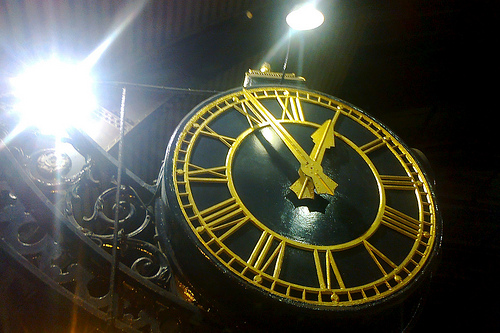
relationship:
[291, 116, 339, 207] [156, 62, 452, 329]
hand on clock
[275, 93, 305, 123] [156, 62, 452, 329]
roman numeral on clock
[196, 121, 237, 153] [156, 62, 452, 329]
roman numeral on clock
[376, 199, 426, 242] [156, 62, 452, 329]
roman numeral on clock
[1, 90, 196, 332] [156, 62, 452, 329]
mount for clock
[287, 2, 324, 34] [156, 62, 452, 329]
light over clock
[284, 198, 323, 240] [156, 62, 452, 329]
reflection on face of clock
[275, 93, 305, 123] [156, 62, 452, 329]
roman numeral on face of clock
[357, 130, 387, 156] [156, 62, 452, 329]
number on face of clock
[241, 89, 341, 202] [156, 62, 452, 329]
hand on clock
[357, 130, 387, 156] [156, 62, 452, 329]
number on clock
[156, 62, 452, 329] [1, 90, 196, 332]
clock connected to a mount